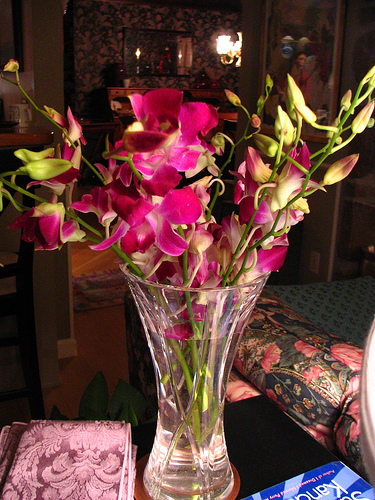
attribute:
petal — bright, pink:
[152, 185, 202, 224]